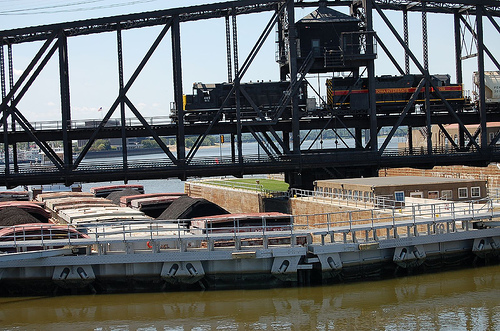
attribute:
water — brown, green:
[9, 291, 116, 328]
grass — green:
[196, 174, 291, 191]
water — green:
[4, 281, 499, 329]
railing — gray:
[0, 198, 499, 255]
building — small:
[285, 6, 382, 76]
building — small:
[313, 175, 489, 216]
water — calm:
[218, 285, 483, 321]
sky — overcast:
[146, 61, 170, 88]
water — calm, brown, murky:
[4, 261, 496, 329]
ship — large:
[82, 144, 166, 159]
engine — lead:
[166, 72, 318, 131]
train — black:
[167, 72, 498, 122]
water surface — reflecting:
[161, 275, 498, 326]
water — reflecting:
[18, 254, 494, 329]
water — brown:
[270, 294, 415, 328]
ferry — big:
[5, 163, 497, 295]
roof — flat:
[317, 175, 487, 186]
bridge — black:
[2, 3, 496, 194]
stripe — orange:
[329, 85, 461, 95]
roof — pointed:
[292, 7, 357, 22]